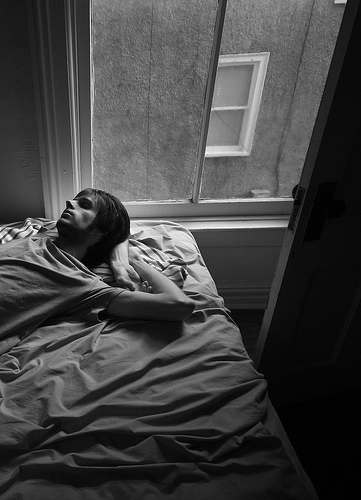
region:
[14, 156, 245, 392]
the guy is lying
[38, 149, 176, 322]
the guy is lying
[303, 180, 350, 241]
A dark door handle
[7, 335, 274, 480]
Crumpled white sheets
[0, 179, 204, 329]
A young man laying on a bed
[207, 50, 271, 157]
One half of a window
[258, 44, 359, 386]
An open wooden door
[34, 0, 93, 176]
The white frame of a window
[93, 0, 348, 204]
An open window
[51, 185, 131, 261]
A man's face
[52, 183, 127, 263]
A man laying down with his eyes closed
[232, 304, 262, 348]
A wooden floor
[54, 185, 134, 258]
the head of a person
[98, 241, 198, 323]
the arm of a person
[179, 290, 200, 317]
the elbow of a person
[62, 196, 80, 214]
the nose of a person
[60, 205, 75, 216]
the mouth of a person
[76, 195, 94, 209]
the eye of a person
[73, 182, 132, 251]
the hair of a person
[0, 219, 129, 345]
a shirt on the person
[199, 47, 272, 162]
a window on the building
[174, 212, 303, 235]
a white window ledge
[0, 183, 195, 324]
a person laying in bed.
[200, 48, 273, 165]
a white window on a building.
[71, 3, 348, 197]
a window in the side of a building.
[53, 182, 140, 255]
a human laying in bed with hair.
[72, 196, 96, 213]
the left eye of a person.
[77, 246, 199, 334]
the left arm of a man.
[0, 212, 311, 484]
a bed inside of a room.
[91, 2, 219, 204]
a pane of glass in a window.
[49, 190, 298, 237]
a window sill on a window.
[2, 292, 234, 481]
a blanket on a bed.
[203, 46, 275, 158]
a window on a building across the way.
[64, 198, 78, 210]
a human nose on a face.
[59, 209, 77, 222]
the mouth of a person.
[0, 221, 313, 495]
a bed with a person in it.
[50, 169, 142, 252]
a human head with hair.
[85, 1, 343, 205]
a large window in a bedroom.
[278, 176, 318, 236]
a door knob.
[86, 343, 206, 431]
a section of a wrinkled blanket.